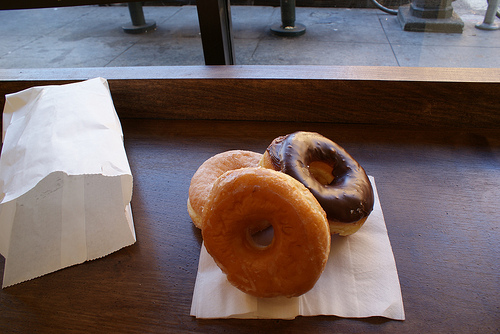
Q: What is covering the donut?
A: Chocolate.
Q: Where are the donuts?
A: On a white napkin.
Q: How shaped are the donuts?
A: Round.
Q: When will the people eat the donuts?
A: When the people are ready.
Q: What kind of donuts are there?
A: Three different kinds: plain, glazed and chocolate.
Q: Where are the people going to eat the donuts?
A: At a coffee shop.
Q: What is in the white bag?
A: Nothing, it is empty.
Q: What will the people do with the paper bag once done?
A: Dump the paper bag in the recycle bin.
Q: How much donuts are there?
A: Three.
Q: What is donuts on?
A: Napkin.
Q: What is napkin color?
A: White.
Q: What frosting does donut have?
A: Chocolate.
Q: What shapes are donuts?
A: Round.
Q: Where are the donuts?
A: Table.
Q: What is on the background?
A: Poles.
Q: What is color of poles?
A: Black.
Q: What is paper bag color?
A: White.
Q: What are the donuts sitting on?
A: A napkin.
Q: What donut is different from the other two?
A: The chocolate one.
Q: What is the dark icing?
A: Chocolate.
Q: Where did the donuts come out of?
A: The white bag.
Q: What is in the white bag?
A: Nothing.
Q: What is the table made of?
A: Wood.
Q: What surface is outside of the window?
A: Sidewalk.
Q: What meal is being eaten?
A: Breakfast.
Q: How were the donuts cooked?
A: They were fried.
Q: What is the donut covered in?
A: Chocolate.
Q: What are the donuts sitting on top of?
A: Paper napkin.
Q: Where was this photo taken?
A: In a cafe.